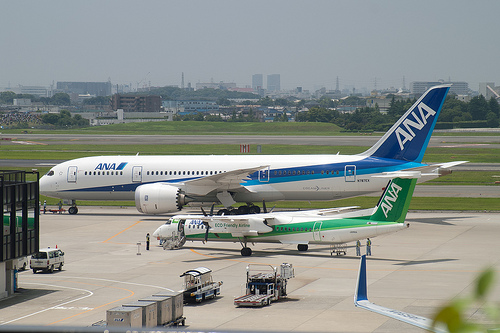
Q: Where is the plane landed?
A: The runway.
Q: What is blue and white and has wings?
A: The plane.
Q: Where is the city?
A: Behind the airplane.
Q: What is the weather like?
A: Overcast.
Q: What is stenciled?
A: ANA.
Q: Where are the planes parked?
A: Next to each other.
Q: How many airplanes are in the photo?
A: 2.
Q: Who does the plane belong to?
A: ANA.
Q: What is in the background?
A: City.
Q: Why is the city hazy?
A: Smog.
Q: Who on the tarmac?
A: Airline personnel.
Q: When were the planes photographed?
A: Daytime.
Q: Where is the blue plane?
A: Behind the green one.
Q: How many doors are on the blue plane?
A: 4.